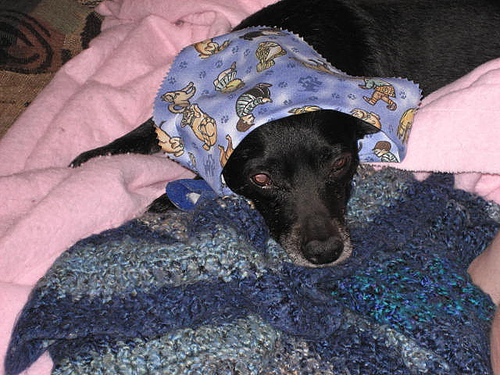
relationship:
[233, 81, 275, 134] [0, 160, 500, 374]
animated character on blue scarf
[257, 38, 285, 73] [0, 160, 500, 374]
character on blue scarf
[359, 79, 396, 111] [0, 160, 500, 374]
character on blue scarf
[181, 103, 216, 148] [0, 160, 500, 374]
character on blue scarf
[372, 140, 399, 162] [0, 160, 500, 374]
character on blue scarf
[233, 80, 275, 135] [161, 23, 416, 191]
animated character on blue scarf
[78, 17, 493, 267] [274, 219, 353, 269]
dog has mouth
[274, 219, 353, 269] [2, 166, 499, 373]
mouth on blanket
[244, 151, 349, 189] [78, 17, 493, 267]
brown eyes of dog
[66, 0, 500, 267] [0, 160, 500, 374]
dog wearing blue scarf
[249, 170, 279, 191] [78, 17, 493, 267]
brown eyes on dog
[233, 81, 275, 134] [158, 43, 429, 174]
animated character printed on bib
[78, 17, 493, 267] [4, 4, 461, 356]
dog laying on blanket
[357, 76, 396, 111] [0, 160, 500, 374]
character printed on blue scarf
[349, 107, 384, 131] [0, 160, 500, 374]
character printed on blue scarf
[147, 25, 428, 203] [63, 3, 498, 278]
bib laying on dog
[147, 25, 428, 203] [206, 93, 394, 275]
bib laying on head